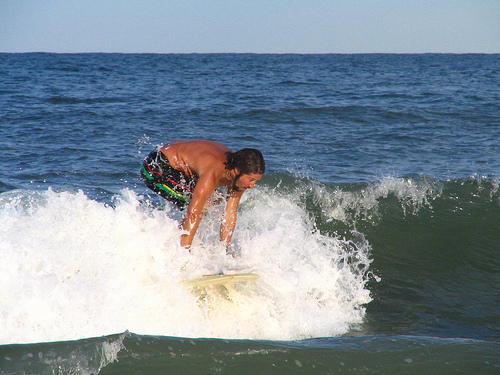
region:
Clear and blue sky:
[2, 1, 497, 57]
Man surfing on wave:
[101, 111, 281, 306]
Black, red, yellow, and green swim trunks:
[126, 130, 206, 220]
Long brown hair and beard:
[220, 135, 268, 203]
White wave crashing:
[5, 183, 370, 346]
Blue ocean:
[5, 48, 496, 370]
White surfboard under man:
[147, 250, 272, 325]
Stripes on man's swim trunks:
[137, 156, 198, 212]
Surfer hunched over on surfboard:
[130, 125, 281, 283]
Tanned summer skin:
[162, 131, 242, 243]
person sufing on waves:
[63, 88, 380, 340]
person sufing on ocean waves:
[80, 98, 342, 330]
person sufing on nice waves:
[73, 112, 370, 334]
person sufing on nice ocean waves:
[75, 96, 361, 341]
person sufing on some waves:
[65, 96, 363, 347]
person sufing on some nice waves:
[50, 66, 384, 336]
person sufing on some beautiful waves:
[65, 104, 347, 340]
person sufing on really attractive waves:
[40, 86, 363, 335]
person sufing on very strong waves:
[90, 81, 345, 342]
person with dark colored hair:
[217, 140, 278, 203]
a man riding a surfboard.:
[129, 135, 285, 272]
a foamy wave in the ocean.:
[0, 172, 387, 357]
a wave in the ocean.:
[0, 171, 499, 355]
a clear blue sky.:
[0, 1, 498, 51]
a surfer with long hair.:
[220, 141, 279, 204]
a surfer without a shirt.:
[161, 114, 285, 267]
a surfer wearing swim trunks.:
[126, 135, 200, 217]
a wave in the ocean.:
[199, 97, 423, 137]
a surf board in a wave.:
[196, 251, 284, 330]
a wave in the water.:
[24, 63, 180, 118]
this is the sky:
[183, 5, 448, 43]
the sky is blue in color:
[237, 3, 385, 50]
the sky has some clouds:
[242, 7, 353, 41]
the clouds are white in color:
[278, 5, 412, 52]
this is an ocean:
[6, 51, 498, 135]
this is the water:
[317, 61, 441, 166]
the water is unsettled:
[293, 63, 375, 133]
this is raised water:
[13, 189, 113, 354]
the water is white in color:
[23, 214, 84, 286]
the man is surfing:
[123, 138, 256, 360]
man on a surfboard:
[132, 111, 320, 331]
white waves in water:
[62, 195, 161, 300]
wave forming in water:
[373, 176, 478, 297]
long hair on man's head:
[186, 155, 275, 217]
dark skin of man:
[190, 138, 242, 206]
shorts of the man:
[123, 148, 187, 217]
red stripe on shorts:
[163, 165, 184, 191]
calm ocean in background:
[329, 68, 416, 130]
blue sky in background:
[245, 7, 339, 54]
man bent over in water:
[156, 149, 273, 269]